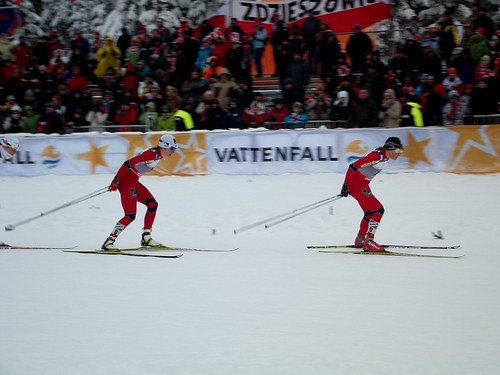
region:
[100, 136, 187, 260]
cross country racer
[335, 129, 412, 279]
cross country racer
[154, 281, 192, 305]
white snow on the ground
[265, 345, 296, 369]
white snow on the ground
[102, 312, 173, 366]
white snow on the ground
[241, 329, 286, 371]
white snow on the ground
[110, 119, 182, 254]
skier during race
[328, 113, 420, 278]
skier during race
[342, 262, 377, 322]
white snow on the ground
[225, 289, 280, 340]
white snow on the ground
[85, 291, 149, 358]
white snow on the ground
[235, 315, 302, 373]
white snow on the ground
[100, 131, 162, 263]
cross country racer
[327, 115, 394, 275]
cross country racer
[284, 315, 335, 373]
white snow on hill side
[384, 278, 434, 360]
white snow on hill side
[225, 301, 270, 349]
white snow on hill side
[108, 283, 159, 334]
white snow on hill side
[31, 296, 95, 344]
white snow on hill side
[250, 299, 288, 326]
white snow on hill side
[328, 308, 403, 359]
white snow on hill side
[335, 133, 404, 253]
skier in red facing right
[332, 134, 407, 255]
skier in red bent slightly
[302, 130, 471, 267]
skier on skis pointing right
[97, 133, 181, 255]
skier in red behind first skier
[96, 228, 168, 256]
yellow ski boots on second skier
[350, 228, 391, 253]
red ski boots on first skier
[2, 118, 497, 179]
barrier fence behind skiers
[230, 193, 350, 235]
two ski poles at a diagonal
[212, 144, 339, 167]
VATTENFALL written on barrier fence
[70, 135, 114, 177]
yellow star on fence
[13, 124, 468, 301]
skiiers in a race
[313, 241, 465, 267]
skiis in the snow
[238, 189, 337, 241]
ski poles in skiiers hands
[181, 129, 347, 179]
banner at a ski slope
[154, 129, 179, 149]
helmet of a skiier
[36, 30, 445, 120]
spectators at a ski slope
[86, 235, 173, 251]
boots on a skiier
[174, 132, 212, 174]
star on a banner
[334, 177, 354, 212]
gloves on a skiier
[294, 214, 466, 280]
skis on the ground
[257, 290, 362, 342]
white snow on ground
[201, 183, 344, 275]
ski poles in hand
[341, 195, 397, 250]
legs of the man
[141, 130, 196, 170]
white hat on person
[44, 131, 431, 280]
two people wearing red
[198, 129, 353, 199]
word on the sign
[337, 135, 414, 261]
skier in black hat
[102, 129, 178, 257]
skier with a white helmet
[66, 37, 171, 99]
people in the crowd standing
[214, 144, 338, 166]
the word "Vanttenfall" in black lettering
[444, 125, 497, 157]
large yellow star with white outline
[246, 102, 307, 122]
people in the crowd sitting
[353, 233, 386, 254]
red boots belonging to first skier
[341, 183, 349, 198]
black gloves on skiers hand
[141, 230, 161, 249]
white boots on skiers left foot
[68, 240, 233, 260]
skis worn by human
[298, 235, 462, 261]
skis worn by human